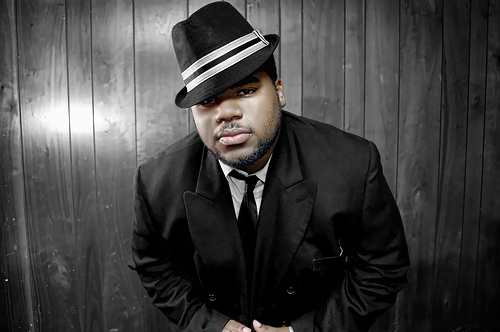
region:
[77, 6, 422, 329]
man standing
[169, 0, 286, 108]
man wearing black cap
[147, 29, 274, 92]
white color line in the cap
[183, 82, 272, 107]
it is man eye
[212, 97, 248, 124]
it is man nose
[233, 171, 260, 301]
man wearing tie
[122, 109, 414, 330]
man wearing black coat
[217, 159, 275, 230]
man wearing white shirt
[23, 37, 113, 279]
it is black color floor shit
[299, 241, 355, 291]
it is a coat pocket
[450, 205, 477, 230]
part of a wall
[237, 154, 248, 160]
part of a chin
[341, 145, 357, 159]
part of a shoulder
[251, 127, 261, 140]
part of a cheek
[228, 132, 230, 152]
part of a nose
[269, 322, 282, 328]
part of a thumb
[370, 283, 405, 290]
edge of an elbow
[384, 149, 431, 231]
pat of a wod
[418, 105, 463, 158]
part of a lin e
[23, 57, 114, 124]
the wall is clean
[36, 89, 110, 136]
the wall is shiny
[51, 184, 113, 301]
the wall is wooden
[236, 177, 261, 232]
this is a tie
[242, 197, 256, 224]
the tie is black in color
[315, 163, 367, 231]
this is a coat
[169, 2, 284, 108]
this is a hat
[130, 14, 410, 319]
this is a man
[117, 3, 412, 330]
A man in a suit wearing a hat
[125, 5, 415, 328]
A man in a suit wearing a hat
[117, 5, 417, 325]
A man in a suit wearing a hat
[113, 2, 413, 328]
A man in a suit wearing a hat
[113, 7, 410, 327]
A man in a suit wearing a hat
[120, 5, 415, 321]
A man in a suit wearing a hat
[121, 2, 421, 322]
A man in a suit wearing a hat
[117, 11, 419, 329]
A man in a suit wearing a hat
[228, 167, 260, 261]
The tie the man is wearing.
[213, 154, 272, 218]
The white shirt the man is wearing.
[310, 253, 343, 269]
The right pocket on the man's jacket.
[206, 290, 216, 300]
The left button on the man's jacket.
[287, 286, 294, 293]
The right button on the man's jacket.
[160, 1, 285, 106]
The black hat the man is wearing.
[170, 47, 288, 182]
Face of a person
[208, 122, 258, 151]
Mouth of a person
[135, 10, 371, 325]
This is a person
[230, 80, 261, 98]
Eye of a person